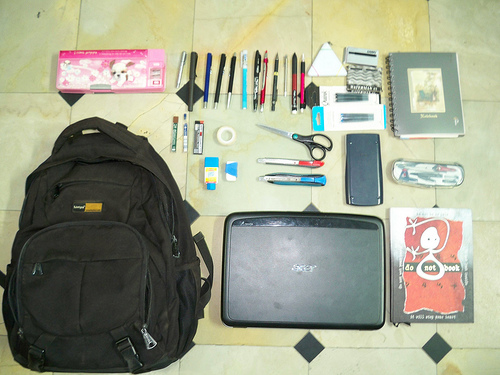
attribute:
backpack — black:
[2, 115, 216, 370]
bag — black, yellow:
[4, 115, 214, 374]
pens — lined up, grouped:
[174, 50, 303, 113]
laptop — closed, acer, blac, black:
[220, 210, 385, 330]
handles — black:
[296, 132, 332, 160]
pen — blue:
[240, 49, 248, 111]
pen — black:
[186, 49, 197, 112]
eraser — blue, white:
[202, 154, 237, 189]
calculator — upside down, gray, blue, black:
[342, 131, 384, 207]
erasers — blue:
[201, 153, 237, 193]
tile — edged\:
[1, 1, 499, 371]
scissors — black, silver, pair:
[254, 121, 331, 161]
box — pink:
[58, 47, 166, 92]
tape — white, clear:
[214, 126, 234, 145]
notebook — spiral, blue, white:
[381, 50, 466, 143]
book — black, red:
[387, 205, 473, 323]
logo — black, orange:
[72, 199, 108, 213]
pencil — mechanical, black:
[271, 53, 280, 110]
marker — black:
[288, 50, 299, 117]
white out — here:
[259, 174, 324, 186]